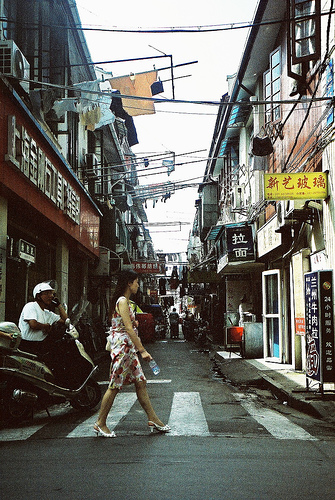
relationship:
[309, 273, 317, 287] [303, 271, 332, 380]
character on sign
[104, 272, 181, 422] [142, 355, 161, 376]
woman holding bottle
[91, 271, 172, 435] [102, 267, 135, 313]
woman with hair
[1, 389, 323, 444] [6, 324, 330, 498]
crosswalk in street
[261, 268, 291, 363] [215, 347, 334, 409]
door on sidewalk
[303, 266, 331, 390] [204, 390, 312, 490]
bus on sidewalk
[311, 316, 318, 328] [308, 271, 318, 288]
character on sign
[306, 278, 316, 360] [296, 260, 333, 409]
foreign character on sign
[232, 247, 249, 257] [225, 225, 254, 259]
character on sign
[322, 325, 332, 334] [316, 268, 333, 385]
foreing character on sign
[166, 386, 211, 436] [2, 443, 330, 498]
line on pavement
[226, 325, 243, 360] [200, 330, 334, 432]
orange chair on sidewalk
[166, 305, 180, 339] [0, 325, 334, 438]
woman in alley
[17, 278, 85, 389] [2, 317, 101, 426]
man on a motorcycle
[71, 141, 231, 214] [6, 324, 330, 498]
clothesline across street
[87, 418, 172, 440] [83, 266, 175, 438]
dress shoes on woman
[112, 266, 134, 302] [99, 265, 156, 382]
hair of woman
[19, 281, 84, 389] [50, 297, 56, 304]
man using cell phone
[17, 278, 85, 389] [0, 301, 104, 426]
man on motorcycle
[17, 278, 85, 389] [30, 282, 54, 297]
man wearing helmet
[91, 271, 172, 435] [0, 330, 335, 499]
woman walking across sidewalk